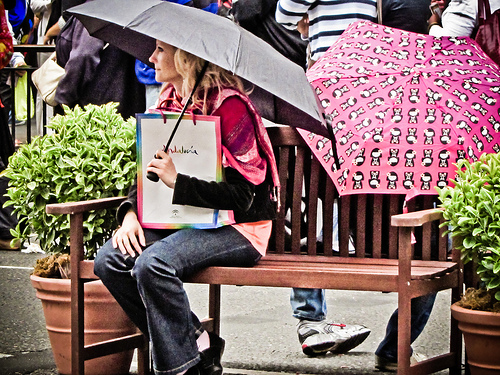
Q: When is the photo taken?
A: Daytime.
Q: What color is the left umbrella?
A: Black.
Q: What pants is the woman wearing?
A: Jeans.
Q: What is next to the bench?
A: Plants.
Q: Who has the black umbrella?
A: The woman.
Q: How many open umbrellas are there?
A: Two.